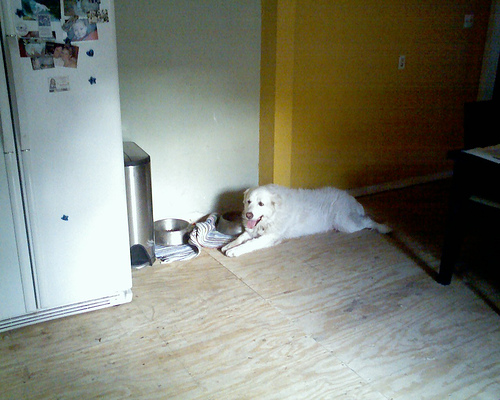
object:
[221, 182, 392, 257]
dog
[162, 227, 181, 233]
dog food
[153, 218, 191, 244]
bowl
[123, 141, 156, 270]
garbage can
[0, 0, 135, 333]
fridge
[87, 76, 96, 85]
magnet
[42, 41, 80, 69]
photograph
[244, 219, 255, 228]
tongue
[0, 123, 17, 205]
handles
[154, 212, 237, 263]
rug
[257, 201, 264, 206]
eyes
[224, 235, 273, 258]
front legs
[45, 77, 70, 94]
pictures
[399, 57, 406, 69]
socket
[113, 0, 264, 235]
wall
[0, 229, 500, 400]
ground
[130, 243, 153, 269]
pedal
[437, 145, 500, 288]
table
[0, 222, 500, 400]
floor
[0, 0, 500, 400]
kitchen